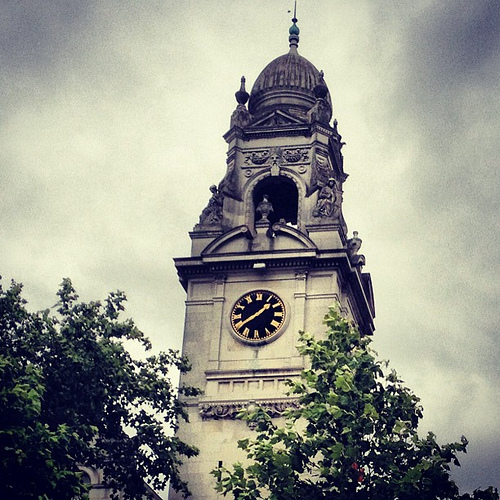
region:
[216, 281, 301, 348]
a large clock with golden numbers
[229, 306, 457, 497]
a tree with green leaves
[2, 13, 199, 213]
clouds in the sky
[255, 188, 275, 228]
a statue on a clock tower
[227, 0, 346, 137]
cathedral roof on a clock tower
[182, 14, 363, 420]
a large clock tower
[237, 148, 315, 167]
engravings on a clock tower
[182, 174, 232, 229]
statue on the side of clock tower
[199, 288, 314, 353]
a large clock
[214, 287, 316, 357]
large clock with golden hands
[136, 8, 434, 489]
ornate stone clock tower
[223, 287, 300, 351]
clock face reading 1:39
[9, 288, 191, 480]
tall green tree growing alongside a tower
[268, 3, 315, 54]
ornate spire on a tower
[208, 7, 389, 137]
rounded dome atop a tower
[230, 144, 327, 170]
face carved into the stone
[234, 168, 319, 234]
arch in the stone tower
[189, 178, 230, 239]
stone angel on the tower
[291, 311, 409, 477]
green tree growing next to a tower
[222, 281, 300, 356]
cock face with roman numerals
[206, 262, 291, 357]
The clock is black.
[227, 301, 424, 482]
The leaves are green.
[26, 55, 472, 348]
The sky is grey.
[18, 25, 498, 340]
The sky is cloudy.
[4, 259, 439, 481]
The trees are in front of the tower.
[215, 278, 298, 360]
The clock says 1:40.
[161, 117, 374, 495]
The tower is grey.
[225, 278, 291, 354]
The hands are gold.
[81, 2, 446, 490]
The tower is taller then the trees.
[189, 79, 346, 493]
The building is stone.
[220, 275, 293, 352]
A black clock face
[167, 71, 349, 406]
A tall clock tower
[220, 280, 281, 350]
Roman numerals on a clock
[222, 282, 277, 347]
Gold colored clock hands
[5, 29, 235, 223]
A cloudy sky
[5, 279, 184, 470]
A green leafy tree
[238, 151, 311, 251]
An arched opening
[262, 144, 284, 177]
A face above an opening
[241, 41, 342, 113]
A dome on top of a clock tower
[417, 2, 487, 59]
Dark blue sky peeking through the clouds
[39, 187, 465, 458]
Picture taken outside.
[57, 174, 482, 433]
Picture taken during the day.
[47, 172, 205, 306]
It is a cloudy day.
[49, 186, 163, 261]
The clouds are grey and white.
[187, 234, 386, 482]
A old clock tower behind the trees.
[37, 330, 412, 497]
The trees are green.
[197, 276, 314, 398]
The clock is showing 1:40.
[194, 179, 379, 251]
The tower is ornate.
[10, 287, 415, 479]
The tree is full of leaves.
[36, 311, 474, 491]
The trees are green and full.